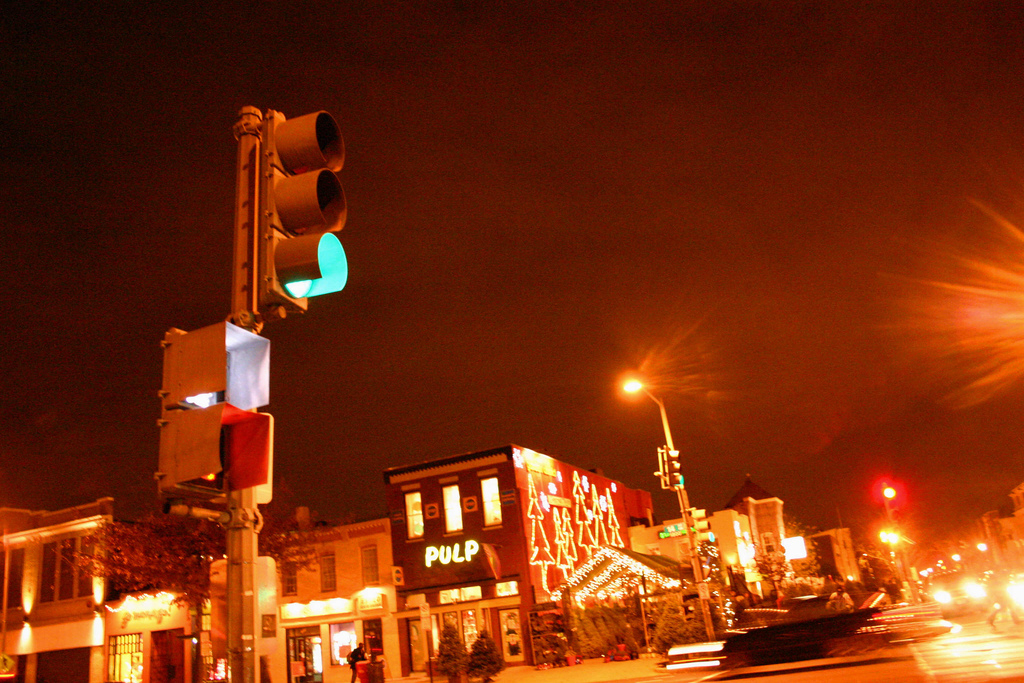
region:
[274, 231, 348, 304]
the green traffic lights appears blueish against the brown background.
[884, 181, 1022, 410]
light rays from a brightly lit street light show at the side.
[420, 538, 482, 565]
The letters that form the word PULP show brightly against the building.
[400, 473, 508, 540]
A row of three tall windows on the top floor of the building are all lit.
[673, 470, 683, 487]
Another green traffic light from far away shows brightly against the brown background.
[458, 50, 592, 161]
a view of dark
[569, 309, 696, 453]
lights on the top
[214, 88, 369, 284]
a view of traffic signal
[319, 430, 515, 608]
a text with lights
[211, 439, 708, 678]
a view of building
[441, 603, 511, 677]
a view of trees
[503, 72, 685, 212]
a view of sky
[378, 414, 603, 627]
a view of windows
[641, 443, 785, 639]
a view of pole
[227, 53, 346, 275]
lights on the top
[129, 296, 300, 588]
a view of traffic signals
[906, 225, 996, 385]
a view of focus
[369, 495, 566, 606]
a view of name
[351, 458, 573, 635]
name on the buiding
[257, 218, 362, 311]
green light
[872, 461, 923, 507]
red light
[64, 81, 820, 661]
this is a city scene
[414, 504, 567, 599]
the letters are lit up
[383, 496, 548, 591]
the letters are white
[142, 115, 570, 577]
the trafffic light is green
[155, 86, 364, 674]
streetlight with a green light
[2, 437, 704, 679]
downtown area of a city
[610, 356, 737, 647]
tall streetlights on a city street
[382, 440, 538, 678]
building front with the word PULP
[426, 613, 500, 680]
two trees next to each other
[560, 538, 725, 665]
a small Christmas tree lot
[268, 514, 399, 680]
a small store front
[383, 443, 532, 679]
two Christmas trees in front of a building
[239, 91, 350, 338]
green traffic light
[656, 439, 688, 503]
green traffic light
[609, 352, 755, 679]
light post with overhead light and traffic light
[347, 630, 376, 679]
person walking down the sidewalk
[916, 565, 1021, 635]
traffic driving at night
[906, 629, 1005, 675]
white stripes on road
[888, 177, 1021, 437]
flare from a nearby bright light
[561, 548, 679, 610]
twinkle lights under a roof